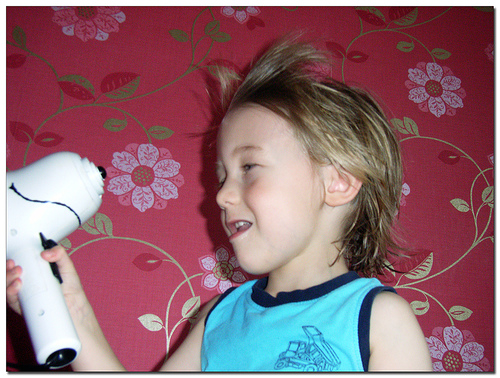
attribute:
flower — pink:
[101, 131, 188, 214]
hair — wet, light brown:
[206, 29, 412, 278]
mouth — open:
[221, 215, 253, 240]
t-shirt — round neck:
[201, 269, 394, 374]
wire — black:
[8, 354, 63, 373]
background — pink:
[13, 9, 496, 349]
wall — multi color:
[10, 8, 494, 350]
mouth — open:
[206, 207, 260, 241]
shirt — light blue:
[190, 272, 371, 374]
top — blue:
[184, 275, 387, 373]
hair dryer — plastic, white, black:
[10, 150, 119, 366]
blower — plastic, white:
[7, 149, 112, 367]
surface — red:
[10, 8, 488, 375]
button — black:
[40, 236, 59, 258]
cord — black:
[40, 354, 74, 370]